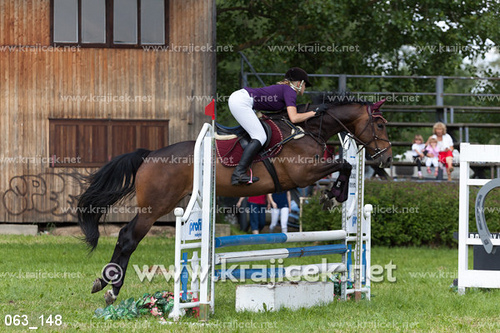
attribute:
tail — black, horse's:
[78, 145, 152, 257]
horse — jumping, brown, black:
[90, 89, 392, 307]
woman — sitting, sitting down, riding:
[426, 122, 456, 172]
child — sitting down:
[422, 133, 441, 169]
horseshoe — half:
[472, 176, 500, 256]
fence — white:
[455, 139, 500, 299]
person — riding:
[225, 66, 323, 187]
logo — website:
[55, 199, 154, 220]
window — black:
[47, 2, 167, 46]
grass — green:
[5, 233, 500, 328]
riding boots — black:
[233, 139, 261, 185]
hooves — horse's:
[326, 185, 348, 207]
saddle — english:
[211, 111, 301, 170]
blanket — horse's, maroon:
[213, 118, 284, 168]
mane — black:
[301, 86, 380, 115]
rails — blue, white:
[214, 225, 346, 279]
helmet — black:
[286, 66, 314, 83]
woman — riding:
[224, 64, 319, 184]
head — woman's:
[284, 66, 318, 97]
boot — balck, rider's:
[234, 138, 261, 185]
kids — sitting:
[409, 134, 442, 173]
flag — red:
[203, 98, 216, 126]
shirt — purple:
[246, 84, 296, 110]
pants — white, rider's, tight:
[224, 90, 271, 147]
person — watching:
[430, 121, 455, 171]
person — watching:
[410, 127, 426, 163]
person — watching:
[424, 135, 442, 176]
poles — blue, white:
[215, 227, 354, 266]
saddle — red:
[200, 120, 283, 178]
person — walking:
[269, 193, 296, 232]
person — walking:
[236, 192, 279, 237]